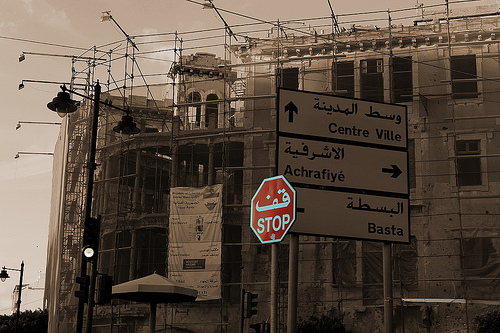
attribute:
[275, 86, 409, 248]
sign — black, white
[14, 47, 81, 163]
lights — overhead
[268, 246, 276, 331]
pole — grey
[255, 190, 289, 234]
print — white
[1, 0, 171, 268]
sky — grey, cloudy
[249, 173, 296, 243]
stop sign — red, white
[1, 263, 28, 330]
streetlight — distant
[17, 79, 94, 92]
light — overhead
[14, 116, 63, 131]
light — overhead